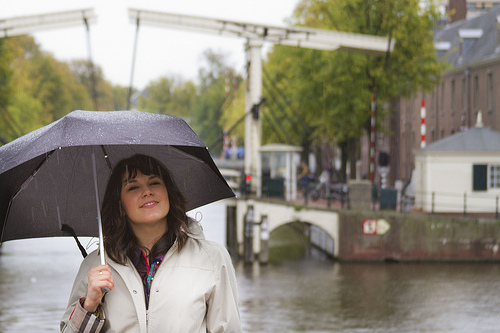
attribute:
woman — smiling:
[95, 161, 183, 256]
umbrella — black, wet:
[1, 94, 239, 250]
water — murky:
[283, 257, 418, 313]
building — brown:
[381, 37, 498, 131]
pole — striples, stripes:
[412, 95, 432, 161]